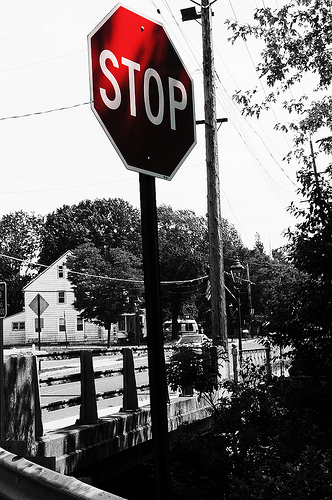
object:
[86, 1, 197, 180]
stop sign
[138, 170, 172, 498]
pole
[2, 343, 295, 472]
bridge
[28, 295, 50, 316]
back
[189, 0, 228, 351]
telephone pole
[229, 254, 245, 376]
street light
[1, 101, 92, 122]
wire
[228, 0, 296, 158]
wire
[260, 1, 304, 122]
wire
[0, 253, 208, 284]
wire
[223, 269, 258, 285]
wire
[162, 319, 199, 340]
van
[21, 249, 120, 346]
house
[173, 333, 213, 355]
car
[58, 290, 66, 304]
window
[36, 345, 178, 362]
railing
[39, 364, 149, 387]
railing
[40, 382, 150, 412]
railing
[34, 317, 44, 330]
street sign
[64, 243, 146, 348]
tree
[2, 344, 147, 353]
yard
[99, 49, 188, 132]
word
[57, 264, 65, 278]
window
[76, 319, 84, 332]
window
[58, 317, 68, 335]
window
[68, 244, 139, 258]
edge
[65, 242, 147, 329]
tree top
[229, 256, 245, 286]
lantern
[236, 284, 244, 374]
post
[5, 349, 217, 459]
shadow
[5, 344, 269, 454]
light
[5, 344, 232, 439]
fence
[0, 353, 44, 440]
column support